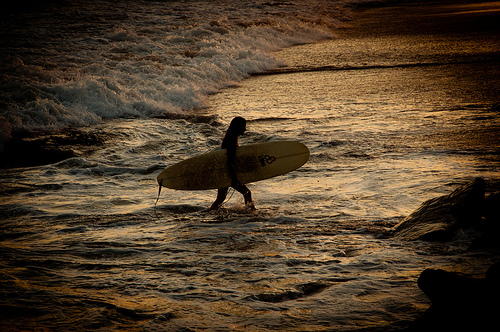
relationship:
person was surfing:
[213, 113, 256, 212] [157, 137, 308, 190]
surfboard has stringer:
[157, 137, 308, 190] [162, 160, 309, 181]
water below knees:
[177, 208, 286, 250] [208, 187, 256, 207]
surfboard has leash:
[157, 137, 308, 190] [153, 179, 237, 207]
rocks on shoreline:
[417, 261, 499, 330] [392, 93, 500, 331]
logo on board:
[256, 152, 277, 164] [248, 138, 311, 174]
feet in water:
[203, 205, 254, 224] [177, 208, 286, 250]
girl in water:
[213, 113, 256, 212] [177, 208, 286, 250]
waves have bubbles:
[24, 74, 214, 122] [45, 106, 149, 109]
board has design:
[157, 137, 308, 190] [260, 149, 279, 169]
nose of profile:
[241, 126, 251, 132] [232, 115, 252, 137]